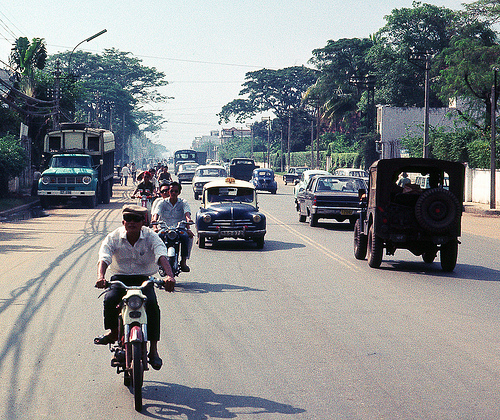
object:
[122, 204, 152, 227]
hat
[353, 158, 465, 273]
car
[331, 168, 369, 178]
sedan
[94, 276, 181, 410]
motorbike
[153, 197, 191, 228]
shirt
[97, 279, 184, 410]
bike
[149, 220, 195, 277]
bike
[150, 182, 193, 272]
man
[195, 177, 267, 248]
taxi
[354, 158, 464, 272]
jeep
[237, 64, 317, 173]
tree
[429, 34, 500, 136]
tree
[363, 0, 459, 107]
tree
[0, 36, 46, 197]
tree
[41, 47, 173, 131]
tree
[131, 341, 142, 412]
tire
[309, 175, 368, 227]
sedan back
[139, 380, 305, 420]
shadow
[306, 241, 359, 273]
line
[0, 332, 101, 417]
road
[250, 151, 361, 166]
hedge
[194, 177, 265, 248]
cars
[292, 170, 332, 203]
cars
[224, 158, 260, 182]
cars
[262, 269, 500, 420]
road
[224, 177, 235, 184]
sign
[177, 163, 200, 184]
car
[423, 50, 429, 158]
pole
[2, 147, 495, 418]
street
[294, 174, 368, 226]
car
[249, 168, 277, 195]
car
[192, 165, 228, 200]
car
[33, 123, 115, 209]
truck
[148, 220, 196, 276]
motorcycle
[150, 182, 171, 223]
people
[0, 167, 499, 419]
ground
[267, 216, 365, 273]
line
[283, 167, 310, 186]
sedan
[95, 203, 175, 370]
man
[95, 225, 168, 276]
shirt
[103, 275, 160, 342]
pants